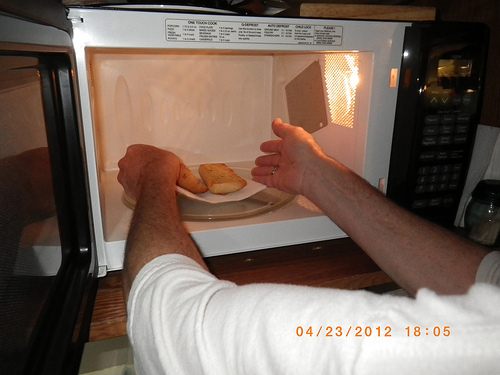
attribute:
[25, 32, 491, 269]
microwave — black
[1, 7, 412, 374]
microwave — white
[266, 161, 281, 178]
ring — silver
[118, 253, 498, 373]
sleeve — white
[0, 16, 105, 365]
door — windowed, black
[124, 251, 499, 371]
sleeves — white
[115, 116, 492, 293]
arms — hairy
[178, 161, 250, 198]
food — rectangular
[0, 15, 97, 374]
microwave door — open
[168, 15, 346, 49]
label — white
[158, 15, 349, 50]
writing — black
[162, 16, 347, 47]
label — white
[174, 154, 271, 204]
paper — white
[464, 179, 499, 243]
container — glass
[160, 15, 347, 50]
instruction — white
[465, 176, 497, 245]
jar — glass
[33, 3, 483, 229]
microwave — black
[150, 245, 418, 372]
shirt — white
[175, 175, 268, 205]
napkin — paper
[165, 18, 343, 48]
words — black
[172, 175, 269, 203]
paper — white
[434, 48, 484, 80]
display screen — plastic, clear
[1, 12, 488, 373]
microwave — white, black